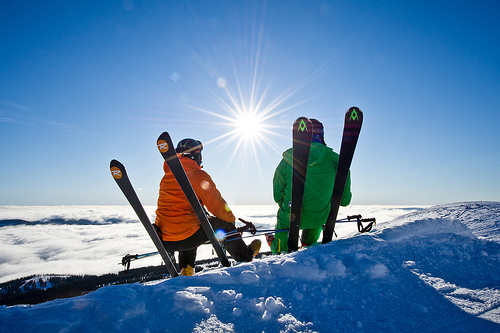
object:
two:
[278, 201, 332, 233]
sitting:
[152, 222, 216, 252]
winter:
[227, 72, 346, 108]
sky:
[350, 14, 433, 110]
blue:
[30, 45, 69, 65]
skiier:
[153, 138, 262, 277]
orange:
[157, 196, 184, 212]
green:
[313, 167, 328, 214]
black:
[183, 140, 196, 149]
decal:
[296, 119, 309, 134]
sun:
[221, 102, 286, 146]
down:
[160, 258, 331, 300]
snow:
[208, 273, 261, 332]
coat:
[273, 142, 353, 227]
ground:
[79, 221, 182, 265]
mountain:
[394, 200, 500, 253]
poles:
[247, 229, 289, 232]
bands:
[118, 253, 138, 275]